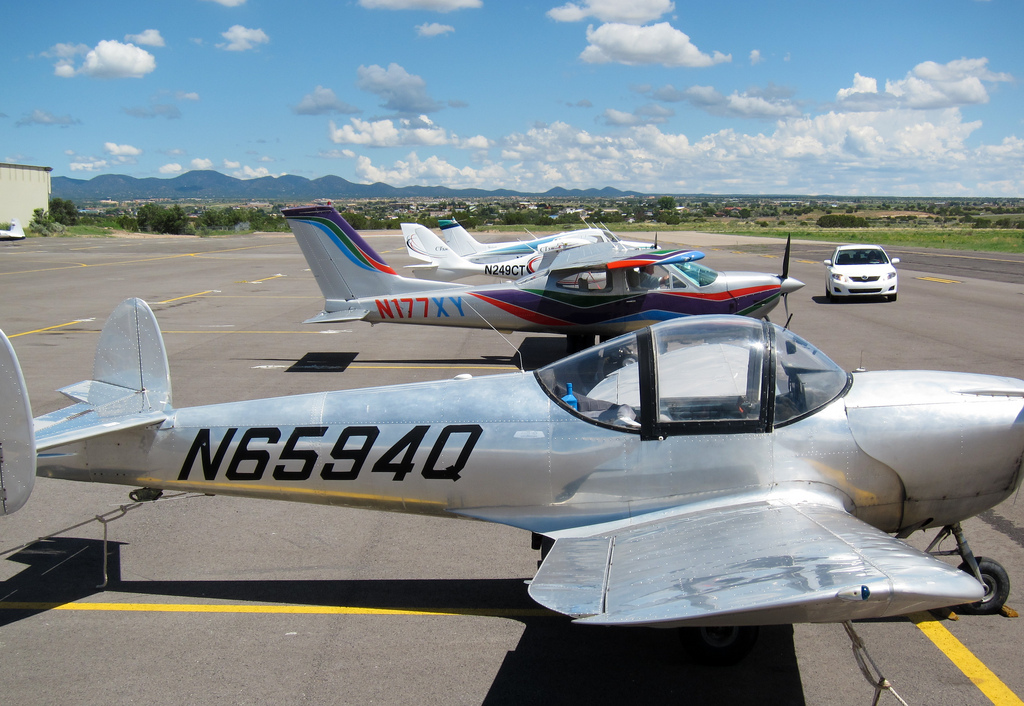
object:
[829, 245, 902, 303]
car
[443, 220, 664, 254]
airplane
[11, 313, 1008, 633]
airplane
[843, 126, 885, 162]
clouds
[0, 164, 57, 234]
building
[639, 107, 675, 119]
cloud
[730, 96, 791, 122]
cloud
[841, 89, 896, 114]
cloud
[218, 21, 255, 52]
cloud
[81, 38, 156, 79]
cloud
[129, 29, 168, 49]
cloud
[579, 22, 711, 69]
cloud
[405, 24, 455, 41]
cloud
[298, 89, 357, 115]
cloud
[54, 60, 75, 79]
cloud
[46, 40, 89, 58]
cloud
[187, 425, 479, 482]
writing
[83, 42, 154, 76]
cloud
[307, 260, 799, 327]
airplane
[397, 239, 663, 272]
airplane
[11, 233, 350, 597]
runway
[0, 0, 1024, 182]
sky